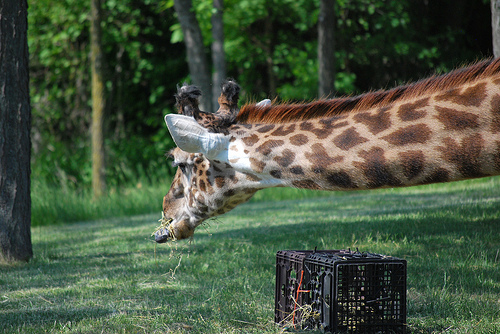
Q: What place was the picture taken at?
A: It was taken at the field.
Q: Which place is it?
A: It is a field.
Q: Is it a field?
A: Yes, it is a field.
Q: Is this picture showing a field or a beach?
A: It is showing a field.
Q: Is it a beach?
A: No, it is a field.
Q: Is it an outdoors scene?
A: Yes, it is outdoors.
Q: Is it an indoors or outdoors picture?
A: It is outdoors.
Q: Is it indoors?
A: No, it is outdoors.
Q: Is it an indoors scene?
A: No, it is outdoors.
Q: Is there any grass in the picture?
A: Yes, there is grass.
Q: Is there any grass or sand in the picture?
A: Yes, there is grass.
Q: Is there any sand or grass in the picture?
A: Yes, there is grass.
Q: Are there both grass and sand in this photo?
A: No, there is grass but no sand.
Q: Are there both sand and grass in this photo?
A: No, there is grass but no sand.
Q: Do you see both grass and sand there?
A: No, there is grass but no sand.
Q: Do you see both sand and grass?
A: No, there is grass but no sand.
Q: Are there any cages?
A: No, there are no cages.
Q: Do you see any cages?
A: No, there are no cages.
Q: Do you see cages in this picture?
A: No, there are no cages.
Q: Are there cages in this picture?
A: No, there are no cages.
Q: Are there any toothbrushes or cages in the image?
A: No, there are no cages or toothbrushes.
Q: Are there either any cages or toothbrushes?
A: No, there are no cages or toothbrushes.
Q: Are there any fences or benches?
A: No, there are no fences or benches.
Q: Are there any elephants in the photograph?
A: No, there are no elephants.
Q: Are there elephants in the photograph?
A: No, there are no elephants.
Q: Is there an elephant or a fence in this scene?
A: No, there are no elephants or fences.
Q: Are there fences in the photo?
A: No, there are no fences.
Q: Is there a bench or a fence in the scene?
A: No, there are no fences or benches.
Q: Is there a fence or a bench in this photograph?
A: No, there are no fences or benches.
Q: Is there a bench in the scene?
A: No, there are no benches.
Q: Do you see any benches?
A: No, there are no benches.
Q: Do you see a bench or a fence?
A: No, there are no benches or fences.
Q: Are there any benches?
A: No, there are no benches.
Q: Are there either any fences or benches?
A: No, there are no benches or fences.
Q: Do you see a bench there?
A: No, there are no benches.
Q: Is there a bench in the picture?
A: No, there are no benches.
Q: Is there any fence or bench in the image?
A: No, there are no benches or fences.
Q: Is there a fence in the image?
A: No, there are no fences.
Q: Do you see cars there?
A: No, there are no cars.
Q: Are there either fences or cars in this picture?
A: No, there are no cars or fences.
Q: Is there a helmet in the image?
A: No, there are no helmets.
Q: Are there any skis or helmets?
A: No, there are no helmets or skis.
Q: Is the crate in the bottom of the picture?
A: Yes, the crate is in the bottom of the image.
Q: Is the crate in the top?
A: No, the crate is in the bottom of the image.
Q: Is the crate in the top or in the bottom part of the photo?
A: The crate is in the bottom of the image.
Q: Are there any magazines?
A: No, there are no magazines.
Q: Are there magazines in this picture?
A: No, there are no magazines.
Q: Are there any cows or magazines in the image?
A: No, there are no magazines or cows.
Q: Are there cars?
A: No, there are no cars.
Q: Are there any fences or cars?
A: No, there are no cars or fences.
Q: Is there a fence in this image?
A: No, there are no fences.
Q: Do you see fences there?
A: No, there are no fences.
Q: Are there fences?
A: No, there are no fences.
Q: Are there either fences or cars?
A: No, there are no fences or cars.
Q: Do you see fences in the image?
A: No, there are no fences.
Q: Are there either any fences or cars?
A: No, there are no fences or cars.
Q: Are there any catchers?
A: No, there are no catchers.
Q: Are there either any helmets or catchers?
A: No, there are no catchers or helmets.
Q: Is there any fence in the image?
A: No, there are no fences.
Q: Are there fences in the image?
A: No, there are no fences.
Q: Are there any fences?
A: No, there are no fences.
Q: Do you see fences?
A: No, there are no fences.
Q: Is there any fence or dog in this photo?
A: No, there are no fences or dogs.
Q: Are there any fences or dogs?
A: No, there are no fences or dogs.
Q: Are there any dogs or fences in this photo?
A: No, there are no fences or dogs.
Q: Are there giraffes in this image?
A: Yes, there is a giraffe.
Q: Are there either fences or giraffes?
A: Yes, there is a giraffe.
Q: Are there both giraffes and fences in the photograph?
A: No, there is a giraffe but no fences.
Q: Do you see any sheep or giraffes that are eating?
A: Yes, the giraffe is eating.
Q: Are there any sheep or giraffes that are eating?
A: Yes, the giraffe is eating.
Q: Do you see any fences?
A: No, there are no fences.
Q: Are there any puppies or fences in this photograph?
A: No, there are no fences or puppies.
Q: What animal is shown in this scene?
A: The animal is a giraffe.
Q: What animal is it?
A: The animal is a giraffe.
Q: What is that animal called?
A: That is a giraffe.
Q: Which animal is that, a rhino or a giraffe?
A: That is a giraffe.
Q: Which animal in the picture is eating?
A: The animal is a giraffe.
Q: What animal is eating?
A: The animal is a giraffe.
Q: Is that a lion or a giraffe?
A: That is a giraffe.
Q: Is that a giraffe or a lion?
A: That is a giraffe.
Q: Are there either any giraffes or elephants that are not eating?
A: No, there is a giraffe but it is eating.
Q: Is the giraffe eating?
A: Yes, the giraffe is eating.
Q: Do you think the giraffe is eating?
A: Yes, the giraffe is eating.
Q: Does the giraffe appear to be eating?
A: Yes, the giraffe is eating.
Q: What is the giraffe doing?
A: The giraffe is eating.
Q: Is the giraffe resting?
A: No, the giraffe is eating.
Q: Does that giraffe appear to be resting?
A: No, the giraffe is eating.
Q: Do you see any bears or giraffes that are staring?
A: No, there is a giraffe but it is eating.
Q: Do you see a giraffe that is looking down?
A: No, there is a giraffe but it is eating.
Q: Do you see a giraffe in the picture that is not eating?
A: No, there is a giraffe but it is eating.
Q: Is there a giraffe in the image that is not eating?
A: No, there is a giraffe but it is eating.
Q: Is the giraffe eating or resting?
A: The giraffe is eating.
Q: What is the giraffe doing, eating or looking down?
A: The giraffe is eating.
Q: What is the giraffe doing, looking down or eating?
A: The giraffe is eating.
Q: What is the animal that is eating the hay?
A: The animal is a giraffe.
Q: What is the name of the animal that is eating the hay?
A: The animal is a giraffe.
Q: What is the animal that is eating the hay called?
A: The animal is a giraffe.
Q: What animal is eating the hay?
A: The animal is a giraffe.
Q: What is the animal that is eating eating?
A: The giraffe is eating hay.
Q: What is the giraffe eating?
A: The giraffe is eating hay.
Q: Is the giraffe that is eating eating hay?
A: Yes, the giraffe is eating hay.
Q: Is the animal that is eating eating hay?
A: Yes, the giraffe is eating hay.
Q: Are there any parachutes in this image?
A: No, there are no parachutes.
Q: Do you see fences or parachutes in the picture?
A: No, there are no parachutes or fences.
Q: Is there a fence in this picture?
A: No, there are no fences.